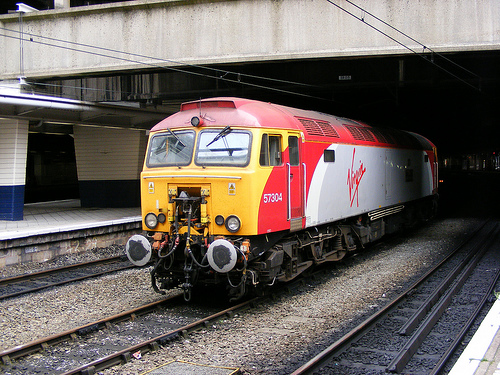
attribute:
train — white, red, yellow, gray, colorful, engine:
[125, 97, 441, 305]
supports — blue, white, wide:
[1, 117, 149, 219]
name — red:
[347, 146, 368, 209]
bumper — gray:
[124, 233, 237, 273]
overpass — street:
[2, 1, 498, 82]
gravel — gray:
[85, 218, 470, 375]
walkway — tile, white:
[1, 198, 144, 242]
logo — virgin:
[344, 146, 369, 206]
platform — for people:
[1, 199, 144, 243]